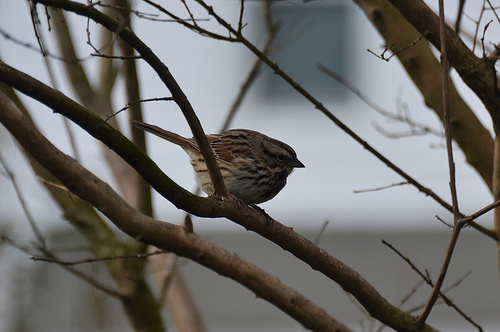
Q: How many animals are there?
A: 1.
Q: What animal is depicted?
A: A bird.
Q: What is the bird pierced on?
A: A branch.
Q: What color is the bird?
A: Brown.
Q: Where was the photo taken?
A: A tree.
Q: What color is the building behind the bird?
A: White.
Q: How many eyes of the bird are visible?
A: 1.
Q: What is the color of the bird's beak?
A: Black.